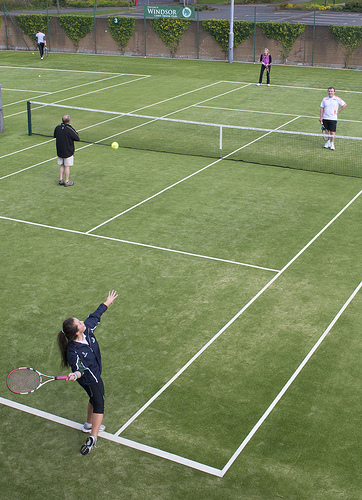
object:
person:
[56, 288, 120, 458]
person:
[52, 112, 80, 189]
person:
[35, 28, 45, 59]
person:
[255, 47, 273, 87]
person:
[317, 85, 346, 151]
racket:
[6, 365, 68, 397]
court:
[0, 49, 362, 498]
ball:
[111, 142, 119, 151]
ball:
[39, 73, 41, 77]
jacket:
[52, 124, 80, 158]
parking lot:
[2, 1, 360, 28]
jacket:
[65, 301, 109, 383]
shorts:
[322, 118, 338, 132]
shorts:
[57, 155, 74, 166]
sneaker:
[80, 436, 95, 456]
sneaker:
[82, 422, 107, 433]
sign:
[144, 5, 194, 20]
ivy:
[17, 14, 51, 40]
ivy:
[57, 13, 94, 47]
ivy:
[106, 16, 136, 50]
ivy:
[147, 17, 189, 54]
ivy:
[200, 17, 253, 55]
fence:
[0, 0, 361, 69]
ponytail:
[56, 327, 68, 370]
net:
[26, 99, 362, 180]